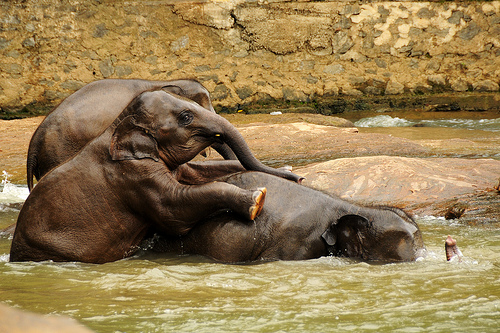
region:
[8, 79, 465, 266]
There are three elephants in the water.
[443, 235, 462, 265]
Elephant nose coming up, out of water.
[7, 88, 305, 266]
Small elephant has foot and trunk on top of larger elephant.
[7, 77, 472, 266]
Three elephants taking a bath.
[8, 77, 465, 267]
Three elephants playing in the water.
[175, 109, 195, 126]
Elephant has black eye that is open and alert.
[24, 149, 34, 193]
The only elephant tail showing in the photo.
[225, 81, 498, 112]
Moss is growing on the rocks.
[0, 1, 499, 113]
There is a high rock with cement wall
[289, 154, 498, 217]
Brown rock located in water.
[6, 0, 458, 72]
a rock behind the elephants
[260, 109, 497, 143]
a wave in the water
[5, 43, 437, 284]
three elephants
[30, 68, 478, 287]
elephants in the water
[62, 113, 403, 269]
an elephant stepping on another elephant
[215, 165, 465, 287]
an elephant under the water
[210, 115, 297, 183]
the trunk of the elephant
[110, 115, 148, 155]
the ear of the elephant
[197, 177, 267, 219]
the leg of the elephant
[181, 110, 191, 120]
the eye of the elephant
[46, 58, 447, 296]
elephants are playing in the water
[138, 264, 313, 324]
the water is murky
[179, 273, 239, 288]
the water is murky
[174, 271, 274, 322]
the water is murky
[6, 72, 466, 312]
Three elephants in a river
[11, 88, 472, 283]
Elephant climbing onto another elephant in a river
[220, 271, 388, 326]
Green river water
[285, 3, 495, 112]
Wet multicolored rocks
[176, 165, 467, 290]
Submerged elephant with trunk as a snorkel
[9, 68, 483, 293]
Three gray elephants playing in the water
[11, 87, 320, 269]
Elephant relaxing its trunk on another elephant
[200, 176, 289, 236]
Orange toenails of elephant's foot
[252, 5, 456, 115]
Rough rocks along the water's edge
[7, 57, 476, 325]
Elephants playing in the murky water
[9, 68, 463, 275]
three elephants playing in water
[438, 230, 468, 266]
the end of an elephants trunk poking out of the water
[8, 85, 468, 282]
one elephant rests his feet on another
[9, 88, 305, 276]
elephant is wet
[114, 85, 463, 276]
elephants trunk rests on the back of another elephant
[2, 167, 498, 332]
elephants are making waves in some water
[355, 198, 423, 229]
tufty black hair on an elephants head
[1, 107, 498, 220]
big flat rocks rise above the water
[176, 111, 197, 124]
eye of an elephant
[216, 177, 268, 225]
elephants foot is orange